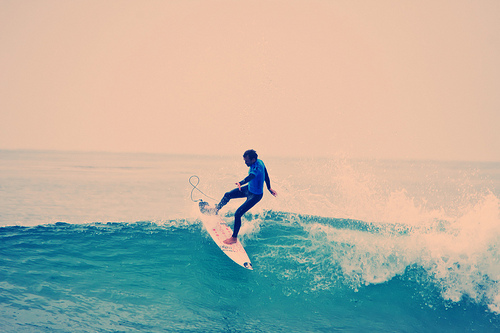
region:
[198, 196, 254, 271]
white and blue surf board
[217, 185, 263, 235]
black rubber surf pants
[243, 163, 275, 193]
blue cotton tee shirt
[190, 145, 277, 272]
person standing on surf board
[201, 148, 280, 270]
man surfing in ocean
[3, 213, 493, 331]
wave formed in ocean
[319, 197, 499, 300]
foam on ocean wave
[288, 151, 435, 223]
mist from ocean water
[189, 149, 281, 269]
man looking at ocean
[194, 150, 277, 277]
man looking at shoreline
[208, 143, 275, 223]
this is a man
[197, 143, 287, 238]
the man is sea surfing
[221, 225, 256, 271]
this is the board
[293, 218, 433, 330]
this is the wave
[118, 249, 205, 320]
the water is green in color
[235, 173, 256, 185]
this is the hand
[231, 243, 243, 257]
the board is white in color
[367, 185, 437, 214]
the water is splashy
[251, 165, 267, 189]
the costume is blue in color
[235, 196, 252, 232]
this is the leg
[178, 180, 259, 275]
The surf board is white.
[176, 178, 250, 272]
The surf board has red lettering.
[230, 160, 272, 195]
He is wearing a blue shirt.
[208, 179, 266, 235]
He is wearing black pants.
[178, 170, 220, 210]
The string is in the air.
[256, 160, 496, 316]
The wave is splashing.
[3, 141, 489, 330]
He is surfing.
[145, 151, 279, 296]
He is standing on the board.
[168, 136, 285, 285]
He is balancing on the board.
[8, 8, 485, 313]
He is in the ocean.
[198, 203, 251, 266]
The surfboard is white.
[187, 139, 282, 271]
A man on the surfboard.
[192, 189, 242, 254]
The man isn't wearing shoes.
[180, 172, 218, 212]
Cord of the surfboard.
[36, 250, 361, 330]
The water is blue.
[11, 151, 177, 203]
The water is grey.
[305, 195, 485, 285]
The water is white.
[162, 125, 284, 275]
The man is surfing.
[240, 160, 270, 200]
The shirt is blue.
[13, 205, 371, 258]
The wave is rising.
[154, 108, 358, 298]
surfer on a ocean wave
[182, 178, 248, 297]
surfboard on a ocean wave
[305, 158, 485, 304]
ocean spray on a ocean wave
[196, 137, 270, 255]
surfer on a ocean wave